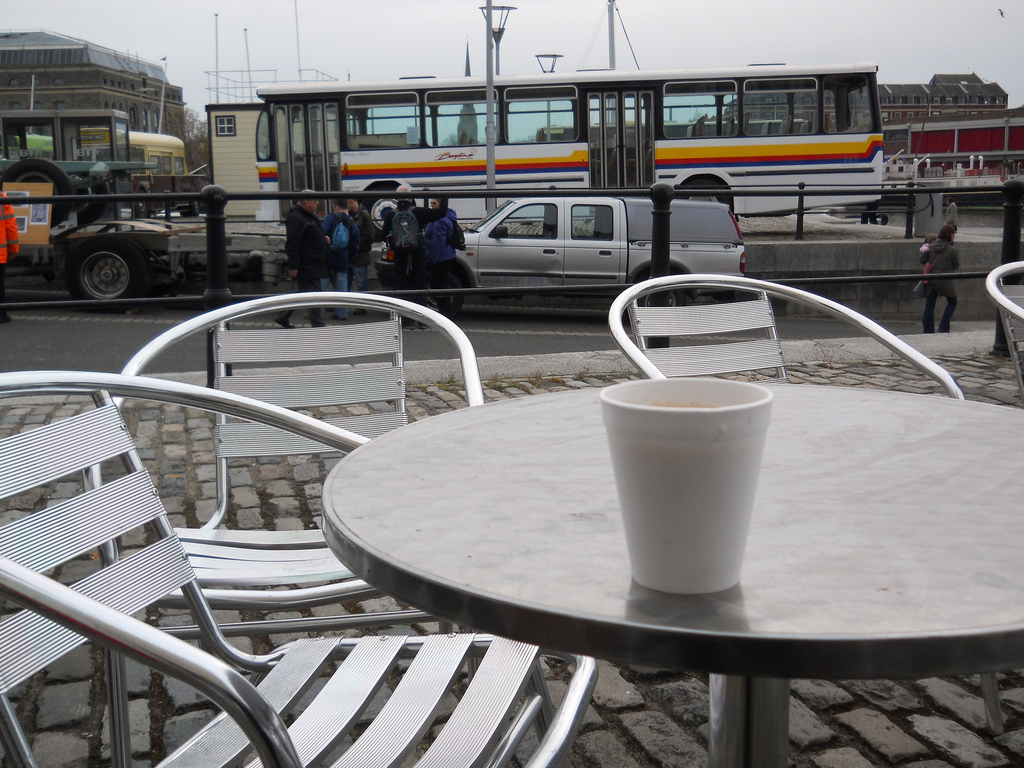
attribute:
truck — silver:
[440, 201, 749, 295]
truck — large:
[10, 199, 192, 305]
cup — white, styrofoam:
[606, 378, 764, 603]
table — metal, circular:
[343, 387, 1016, 744]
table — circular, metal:
[382, 391, 1013, 733]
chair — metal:
[12, 404, 520, 765]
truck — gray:
[466, 206, 763, 300]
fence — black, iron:
[1, 179, 1019, 406]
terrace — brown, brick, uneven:
[1, 324, 1019, 765]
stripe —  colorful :
[251, 132, 882, 182]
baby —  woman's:
[914, 235, 936, 268]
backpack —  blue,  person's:
[325, 220, 356, 253]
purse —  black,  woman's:
[439, 209, 461, 253]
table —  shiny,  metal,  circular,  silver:
[318, 372, 1019, 662]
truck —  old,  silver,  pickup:
[458, 199, 740, 288]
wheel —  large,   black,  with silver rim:
[65, 229, 154, 312]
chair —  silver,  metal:
[601, 266, 978, 394]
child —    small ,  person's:
[912, 237, 938, 289]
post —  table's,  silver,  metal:
[711, 669, 794, 765]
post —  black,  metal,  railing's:
[201, 179, 227, 305]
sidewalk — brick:
[4, 329, 981, 764]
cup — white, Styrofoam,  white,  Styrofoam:
[596, 366, 782, 606]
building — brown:
[4, 24, 192, 176]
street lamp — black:
[471, 3, 515, 75]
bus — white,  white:
[248, 59, 888, 219]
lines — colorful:
[251, 134, 880, 182]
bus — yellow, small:
[54, 117, 186, 176]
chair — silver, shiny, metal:
[8, 356, 602, 765]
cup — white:
[606, 370, 773, 597]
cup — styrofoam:
[578, 365, 780, 605]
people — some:
[265, 180, 471, 301]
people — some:
[305, 191, 474, 285]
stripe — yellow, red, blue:
[336, 139, 872, 152]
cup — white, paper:
[602, 359, 784, 593]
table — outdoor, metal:
[306, 376, 1020, 765]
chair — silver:
[102, 288, 492, 727]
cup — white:
[588, 374, 783, 589]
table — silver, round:
[312, 364, 974, 678]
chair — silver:
[76, 286, 496, 602]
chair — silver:
[599, 262, 962, 384]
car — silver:
[374, 167, 768, 302]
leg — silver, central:
[700, 675, 794, 745]